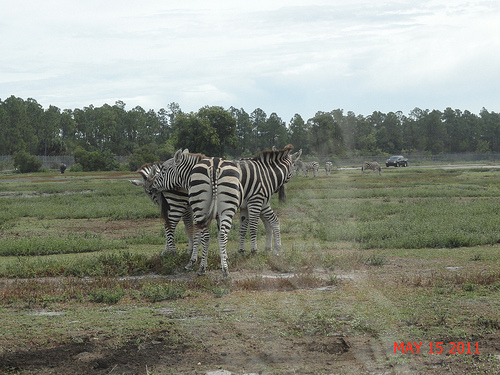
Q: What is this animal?
A: A zebra.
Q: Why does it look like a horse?
A: It has the same body shape but a different skin color pattern.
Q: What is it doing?
A: Eating off the grass.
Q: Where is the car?
A: Near the woods.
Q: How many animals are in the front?
A: Two.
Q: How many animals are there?
A: Five.